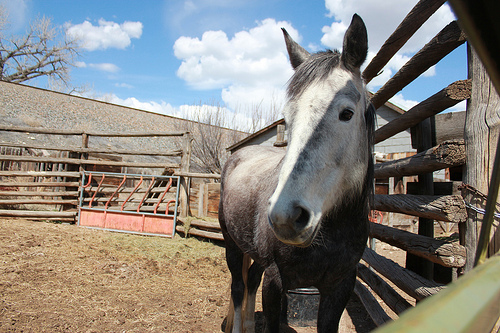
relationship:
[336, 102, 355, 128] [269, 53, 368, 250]
eye on face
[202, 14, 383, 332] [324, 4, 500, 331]
horse by fence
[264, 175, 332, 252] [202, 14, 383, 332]
nose on horse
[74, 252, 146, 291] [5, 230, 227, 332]
hay on ground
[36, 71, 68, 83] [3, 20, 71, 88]
branches on tree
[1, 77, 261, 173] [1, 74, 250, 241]
roof of barn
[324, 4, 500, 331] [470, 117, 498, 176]
fence of wood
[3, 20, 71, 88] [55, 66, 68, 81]
tree has no leaves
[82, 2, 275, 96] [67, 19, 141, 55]
sky has clouds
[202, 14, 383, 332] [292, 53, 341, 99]
horse with hair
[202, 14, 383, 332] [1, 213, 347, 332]
horse on grass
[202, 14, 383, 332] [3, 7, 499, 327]
donkey in pen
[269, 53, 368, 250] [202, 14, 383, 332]
head of donkey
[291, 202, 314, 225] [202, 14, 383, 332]
nostril of donkey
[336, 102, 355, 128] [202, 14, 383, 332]
eye of donkey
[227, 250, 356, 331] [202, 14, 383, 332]
legs of donkey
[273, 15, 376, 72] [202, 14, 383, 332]
ears of donkey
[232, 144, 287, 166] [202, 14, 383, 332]
back of donkey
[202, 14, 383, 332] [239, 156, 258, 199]
donkey has fur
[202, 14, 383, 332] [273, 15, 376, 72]
horse upright ears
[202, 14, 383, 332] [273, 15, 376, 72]
horse has pointed ears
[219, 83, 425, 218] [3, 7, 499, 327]
house on ranch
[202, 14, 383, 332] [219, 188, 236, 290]
horse hanging tail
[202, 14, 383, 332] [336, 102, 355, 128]
horse has a open eye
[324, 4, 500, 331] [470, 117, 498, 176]
fence made of wood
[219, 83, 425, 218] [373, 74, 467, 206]
house in back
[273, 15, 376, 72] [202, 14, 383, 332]
ears on horse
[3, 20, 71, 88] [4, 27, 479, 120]
tree in distance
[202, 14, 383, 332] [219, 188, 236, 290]
horse has tail